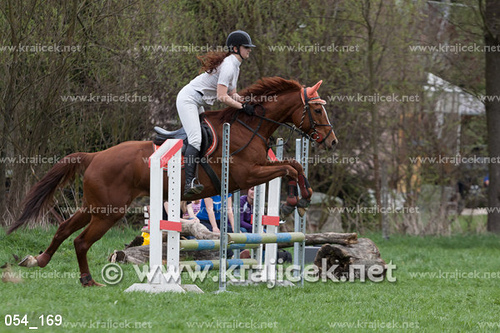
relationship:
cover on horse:
[292, 75, 334, 99] [234, 70, 364, 154]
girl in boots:
[130, 33, 272, 155] [166, 140, 226, 207]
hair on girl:
[187, 45, 250, 83] [164, 28, 255, 167]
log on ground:
[309, 229, 400, 291] [341, 279, 412, 309]